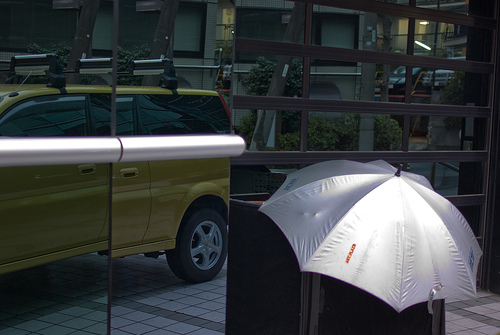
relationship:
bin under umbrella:
[219, 165, 452, 331] [257, 131, 484, 330]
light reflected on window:
[131, 86, 238, 144] [8, 68, 184, 163]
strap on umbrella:
[426, 282, 445, 317] [256, 158, 483, 312]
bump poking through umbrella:
[299, 204, 327, 224] [252, 152, 482, 304]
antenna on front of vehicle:
[8, 66, 39, 98] [3, 71, 243, 291]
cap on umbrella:
[394, 160, 404, 175] [249, 156, 497, 321]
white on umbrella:
[353, 206, 387, 219] [249, 156, 497, 321]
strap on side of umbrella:
[426, 288, 437, 317] [253, 147, 479, 326]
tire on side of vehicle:
[164, 204, 229, 281] [0, 67, 239, 314]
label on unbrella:
[343, 239, 359, 269] [313, 164, 445, 298]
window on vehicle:
[96, 86, 233, 153] [8, 2, 227, 281]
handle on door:
[118, 169, 138, 179] [109, 88, 155, 258]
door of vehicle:
[109, 88, 155, 258] [0, 80, 229, 288]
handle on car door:
[118, 164, 138, 179] [109, 85, 156, 248]